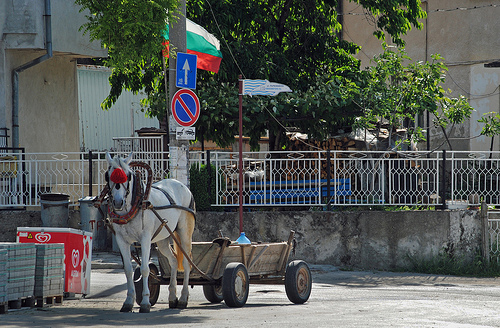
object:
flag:
[160, 7, 223, 74]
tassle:
[110, 165, 128, 183]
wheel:
[285, 260, 312, 304]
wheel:
[203, 285, 224, 303]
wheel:
[133, 263, 160, 306]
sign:
[171, 87, 200, 127]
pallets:
[0, 242, 65, 311]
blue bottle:
[236, 231, 252, 244]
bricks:
[0, 242, 36, 304]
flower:
[108, 167, 128, 182]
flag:
[243, 79, 293, 97]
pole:
[239, 73, 243, 236]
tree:
[73, 0, 423, 202]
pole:
[168, 0, 190, 189]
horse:
[105, 151, 196, 313]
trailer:
[136, 244, 311, 308]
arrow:
[182, 58, 190, 85]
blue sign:
[176, 52, 198, 90]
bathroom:
[95, 150, 204, 315]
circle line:
[170, 88, 200, 126]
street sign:
[239, 74, 293, 236]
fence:
[0, 151, 499, 207]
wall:
[1, 211, 500, 275]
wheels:
[222, 262, 249, 308]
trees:
[333, 46, 499, 200]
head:
[89, 149, 139, 221]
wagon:
[133, 230, 312, 308]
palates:
[183, 230, 296, 280]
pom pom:
[104, 153, 130, 186]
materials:
[34, 243, 65, 307]